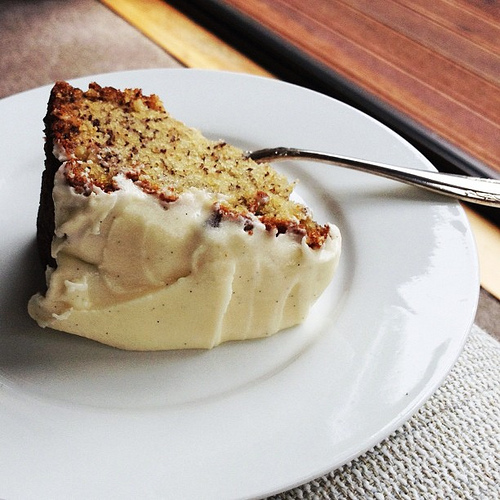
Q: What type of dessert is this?
A: Cake.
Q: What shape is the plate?
A: Circle.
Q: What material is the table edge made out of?
A: Wood.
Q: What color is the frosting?
A: White.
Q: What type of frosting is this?
A: Vanilla.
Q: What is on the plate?
A: Slice of cake.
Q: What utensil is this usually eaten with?
A: Fork.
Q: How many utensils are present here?
A: One.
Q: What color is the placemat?
A: White.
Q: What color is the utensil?
A: Silver.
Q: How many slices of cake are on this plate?
A: One.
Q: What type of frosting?
A: Buttercream.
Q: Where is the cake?
A: On the plate.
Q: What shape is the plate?
A: Round.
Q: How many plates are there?
A: 1.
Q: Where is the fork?
A: On the plate.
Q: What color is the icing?
A: White.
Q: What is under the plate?
A: Placemat.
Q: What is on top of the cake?
A: Icing.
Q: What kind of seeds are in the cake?
A: Poppy.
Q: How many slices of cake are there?
A: 1.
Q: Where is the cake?
A: On the plate.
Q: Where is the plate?
A: On the table.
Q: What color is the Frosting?
A: White.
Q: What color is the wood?
A: Brown.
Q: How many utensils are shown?
A: 1.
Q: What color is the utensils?
A: Silver.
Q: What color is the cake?
A: Brown.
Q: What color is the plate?
A: White.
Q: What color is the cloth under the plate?
A: Grey.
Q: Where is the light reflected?
A: On the fork handle.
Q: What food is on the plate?
A: Cake.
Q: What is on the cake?
A: Icing.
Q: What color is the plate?
A: White.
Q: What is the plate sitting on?
A: Towel.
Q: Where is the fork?
A: On the plate.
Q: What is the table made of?
A: Wood.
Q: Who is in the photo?
A: No one.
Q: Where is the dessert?
A: On the plate.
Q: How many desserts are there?
A: One.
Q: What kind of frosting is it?
A: Vanilla.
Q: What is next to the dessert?
A: Silverware.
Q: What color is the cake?
A: Yellow and brown.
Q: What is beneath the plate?
A: Table.